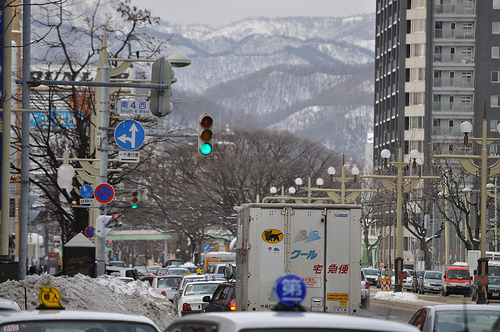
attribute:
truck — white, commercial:
[231, 201, 366, 308]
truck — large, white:
[233, 202, 363, 315]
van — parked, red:
[442, 265, 472, 295]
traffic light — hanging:
[132, 190, 139, 209]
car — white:
[169, 280, 240, 315]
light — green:
[129, 200, 136, 210]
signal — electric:
[196, 115, 213, 159]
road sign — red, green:
[477, 273, 489, 285]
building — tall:
[369, 4, 498, 261]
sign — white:
[112, 118, 146, 152]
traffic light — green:
[198, 112, 216, 156]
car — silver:
[407, 303, 497, 330]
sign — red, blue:
[103, 117, 169, 177]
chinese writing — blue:
[288, 245, 317, 259]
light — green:
[194, 117, 209, 158]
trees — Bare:
[111, 103, 313, 268]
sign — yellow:
[32, 278, 67, 308]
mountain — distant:
[173, 16, 398, 214]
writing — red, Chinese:
[311, 260, 349, 271]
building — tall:
[372, 0, 498, 289]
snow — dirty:
[6, 267, 173, 310]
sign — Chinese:
[116, 98, 154, 119]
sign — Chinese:
[115, 147, 142, 163]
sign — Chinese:
[76, 195, 95, 206]